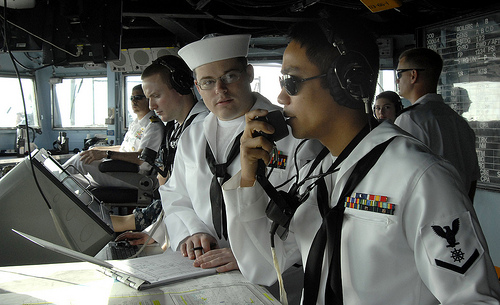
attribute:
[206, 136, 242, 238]
tie — blue, marine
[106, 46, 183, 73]
speakers — set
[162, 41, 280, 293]
man — navy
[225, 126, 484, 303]
uniform — sailor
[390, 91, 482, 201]
uniform — sailor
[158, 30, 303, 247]
uniform — sailor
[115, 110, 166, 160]
uniform — sailor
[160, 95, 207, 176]
uniform — sailor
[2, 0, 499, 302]
ship — navy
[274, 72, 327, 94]
sunglasses — dark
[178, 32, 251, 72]
hat — white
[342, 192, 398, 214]
badge — multicolored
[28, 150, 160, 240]
laptop — silver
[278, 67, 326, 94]
sunglasses — black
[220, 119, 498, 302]
shirt — white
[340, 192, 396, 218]
stripes — navy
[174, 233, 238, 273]
hands — pair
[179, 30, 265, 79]
sailor hat — white